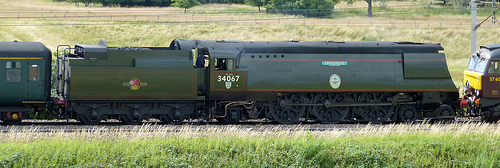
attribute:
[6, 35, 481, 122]
train — freight, yellow, traveling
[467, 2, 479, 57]
pole — metal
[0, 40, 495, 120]
train — black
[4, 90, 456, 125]
wheels — black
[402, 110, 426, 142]
ground — dead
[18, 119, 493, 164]
green grass — tall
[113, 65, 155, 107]
logo — company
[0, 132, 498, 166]
grass — tall, green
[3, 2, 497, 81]
grass — tall, green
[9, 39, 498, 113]
train cars — long, dark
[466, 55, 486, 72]
windshield — train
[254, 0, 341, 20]
trees — green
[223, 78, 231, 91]
shield — blue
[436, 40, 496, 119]
pole — gray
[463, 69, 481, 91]
paint — yellow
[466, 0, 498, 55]
pole — tall, metal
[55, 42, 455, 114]
car — train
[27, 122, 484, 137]
grass — tall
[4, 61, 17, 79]
window — open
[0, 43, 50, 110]
car — black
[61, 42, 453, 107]
car — black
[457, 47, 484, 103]
car — black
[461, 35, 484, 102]
car — yellow, gray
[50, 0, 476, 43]
grass — green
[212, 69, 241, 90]
number — identification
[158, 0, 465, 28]
fence — boundary